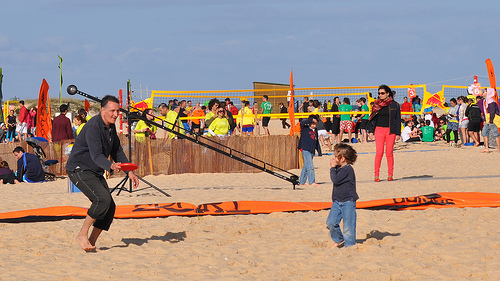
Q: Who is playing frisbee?
A: A man and a boy.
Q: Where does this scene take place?
A: At a beach.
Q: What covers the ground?
A: Sand.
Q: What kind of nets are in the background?
A: Volleyball nets.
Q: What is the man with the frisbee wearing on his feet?
A: Nothing.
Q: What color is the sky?
A: Blue.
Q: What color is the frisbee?
A: Red.